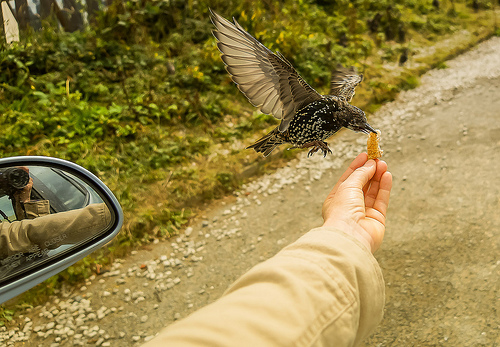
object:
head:
[346, 105, 379, 136]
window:
[0, 159, 106, 281]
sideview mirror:
[0, 153, 127, 307]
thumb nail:
[362, 158, 376, 169]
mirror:
[0, 153, 128, 309]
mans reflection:
[0, 151, 127, 305]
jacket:
[133, 225, 390, 347]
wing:
[201, 2, 323, 134]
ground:
[408, 76, 494, 152]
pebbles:
[138, 208, 228, 291]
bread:
[365, 128, 382, 163]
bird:
[202, 3, 386, 159]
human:
[136, 149, 398, 347]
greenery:
[0, 0, 490, 180]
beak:
[360, 123, 379, 137]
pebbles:
[48, 283, 116, 336]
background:
[0, 0, 500, 38]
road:
[116, 73, 500, 344]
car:
[0, 150, 129, 316]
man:
[0, 165, 113, 283]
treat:
[365, 128, 385, 161]